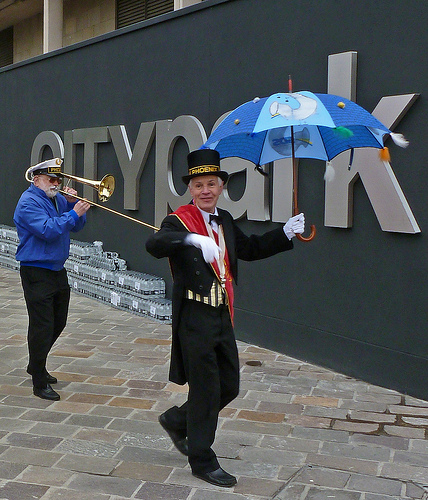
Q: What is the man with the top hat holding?
A: An umbrella.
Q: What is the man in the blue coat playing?
A: A trombone.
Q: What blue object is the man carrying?
A: Umbrella.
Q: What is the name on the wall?
A: Citypark.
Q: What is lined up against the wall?
A: Water bottles.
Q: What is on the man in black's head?
A: A top hat.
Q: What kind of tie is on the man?
A: Bow tie.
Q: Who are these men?
A: Performers.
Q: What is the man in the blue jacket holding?
A: A musical instrument.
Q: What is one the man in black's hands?
A: Gloves.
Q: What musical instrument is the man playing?
A: Trombone.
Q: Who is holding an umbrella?
A: The man in front.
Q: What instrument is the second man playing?
A: Trombone.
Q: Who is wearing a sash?
A: The man with the umbrella.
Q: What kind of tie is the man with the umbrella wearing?
A: Bow tie.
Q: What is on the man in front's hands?
A: White gloves.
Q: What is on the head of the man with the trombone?
A: White captain's hat.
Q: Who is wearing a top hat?
A: The man with the umbrella.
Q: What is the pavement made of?
A: Bricks.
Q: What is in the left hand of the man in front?
A: An umbrella.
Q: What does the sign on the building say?
A: Citypark.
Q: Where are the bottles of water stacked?
A: Against the wall.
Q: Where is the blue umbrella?
A: In the man's hand.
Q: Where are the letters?
A: On a large sign.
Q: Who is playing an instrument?
A: A man.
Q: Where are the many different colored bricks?
A: On the ground.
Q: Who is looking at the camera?
A: A man.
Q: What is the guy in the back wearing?
A: A coat.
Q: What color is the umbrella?
A: Blue.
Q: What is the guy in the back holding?
A: A trombone.